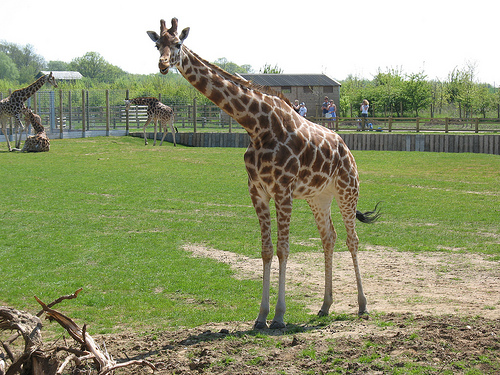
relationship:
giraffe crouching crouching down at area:
[144, 32, 303, 190] [1, 116, 451, 359]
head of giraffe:
[127, 5, 204, 82] [141, 10, 394, 335]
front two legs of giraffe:
[246, 175, 312, 339] [141, 10, 394, 335]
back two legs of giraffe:
[310, 202, 380, 324] [141, 10, 394, 335]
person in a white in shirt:
[353, 99, 376, 129] [355, 97, 374, 112]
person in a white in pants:
[353, 99, 376, 129] [354, 109, 371, 124]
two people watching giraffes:
[316, 91, 345, 127] [0, 59, 77, 165]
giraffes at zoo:
[0, 59, 77, 165] [1, 130, 474, 365]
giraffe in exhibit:
[124, 97, 180, 147] [3, 55, 473, 373]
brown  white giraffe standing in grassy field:
[146, 17, 384, 330] [28, 160, 213, 244]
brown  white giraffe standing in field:
[146, 17, 384, 330] [51, 138, 243, 320]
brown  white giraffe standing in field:
[146, 17, 384, 330] [87, 140, 245, 341]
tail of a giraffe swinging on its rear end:
[353, 208, 392, 229] [326, 128, 362, 212]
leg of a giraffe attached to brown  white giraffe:
[136, 118, 162, 164] [146, 17, 384, 330]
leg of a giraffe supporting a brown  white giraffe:
[263, 196, 314, 359] [146, 17, 384, 330]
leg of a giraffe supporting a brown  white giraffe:
[342, 206, 386, 311] [146, 17, 384, 330]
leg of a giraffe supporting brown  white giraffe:
[306, 194, 350, 322] [146, 17, 384, 330]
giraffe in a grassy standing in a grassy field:
[53, 184, 172, 274] [68, 137, 245, 333]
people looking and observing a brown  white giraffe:
[287, 90, 390, 144] [146, 17, 384, 330]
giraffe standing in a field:
[117, 84, 196, 162] [89, 145, 244, 319]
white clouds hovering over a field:
[256, 6, 344, 49] [103, 140, 231, 339]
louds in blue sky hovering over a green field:
[53, 1, 139, 62] [98, 139, 243, 327]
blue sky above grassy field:
[52, 8, 154, 37] [108, 142, 247, 332]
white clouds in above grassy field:
[219, 6, 332, 48] [119, 140, 244, 332]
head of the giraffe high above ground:
[117, 97, 139, 116] [95, 140, 246, 371]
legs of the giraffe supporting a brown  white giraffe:
[241, 178, 314, 337] [146, 17, 384, 330]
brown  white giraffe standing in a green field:
[146, 17, 384, 330] [88, 139, 243, 372]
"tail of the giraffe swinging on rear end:
[166, 114, 197, 146] [316, 130, 360, 245]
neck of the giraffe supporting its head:
[180, 50, 266, 141] [147, 20, 195, 72]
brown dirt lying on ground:
[308, 307, 466, 363] [382, 152, 484, 372]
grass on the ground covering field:
[349, 233, 478, 326] [72, 140, 245, 336]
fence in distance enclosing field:
[331, 95, 498, 150] [383, 150, 478, 373]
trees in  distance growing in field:
[349, 66, 487, 122] [383, 150, 478, 373]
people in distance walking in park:
[277, 87, 382, 143] [2, 17, 479, 373]